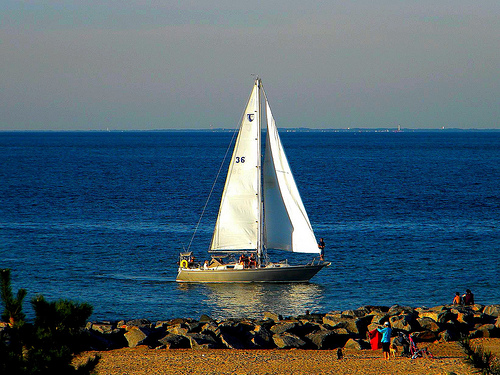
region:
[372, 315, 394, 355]
a person standing on the grass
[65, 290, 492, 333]
rocks in front of the water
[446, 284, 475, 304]
people standing next to the water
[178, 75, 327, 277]
a white boat in the water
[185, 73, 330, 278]
a white sail boat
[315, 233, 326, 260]
a person standing at the front of the boat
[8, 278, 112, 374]
the branch of a tree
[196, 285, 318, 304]
a white reflection in the water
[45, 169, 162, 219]
small waves in the water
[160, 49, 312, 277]
white sail boat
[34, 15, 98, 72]
white clouds in blue sky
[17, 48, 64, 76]
white clouds in blue sky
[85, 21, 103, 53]
white clouds in blue sky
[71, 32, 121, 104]
white clouds in blue sky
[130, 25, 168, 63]
white clouds in blue sky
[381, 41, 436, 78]
white clouds in blue sky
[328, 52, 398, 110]
white clouds in blue sky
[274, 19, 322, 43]
white clouds in blue sky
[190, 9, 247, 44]
white clouds in blue sky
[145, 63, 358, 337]
a sail boat on the water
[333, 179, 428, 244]
the water is blue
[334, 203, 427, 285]
the water is blue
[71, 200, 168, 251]
the water is blue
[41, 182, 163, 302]
the water is blue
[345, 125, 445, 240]
the water is blue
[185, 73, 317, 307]
white sailboat in blue ocean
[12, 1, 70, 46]
white clouds in blue sky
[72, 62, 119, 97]
white clouds in blue sky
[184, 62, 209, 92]
white clouds in blue sky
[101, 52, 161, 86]
white clouds in blue sky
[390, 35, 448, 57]
white clouds in blue sky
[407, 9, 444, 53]
white clouds in blue sky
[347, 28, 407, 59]
white clouds in blue sky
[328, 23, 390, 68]
white clouds in blue sky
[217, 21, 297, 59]
white clouds in blue sky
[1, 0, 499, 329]
The sailboat is in the water.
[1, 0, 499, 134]
The sky is blue.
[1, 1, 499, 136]
The sky is clear.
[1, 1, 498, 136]
The sky is cloudless.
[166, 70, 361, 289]
The sailboat has white masts.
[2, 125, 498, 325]
The water is blue.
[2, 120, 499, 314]
The water is calm.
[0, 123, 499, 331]
The water is tranquil.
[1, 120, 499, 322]
The water is serene.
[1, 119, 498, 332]
The water is subdued.